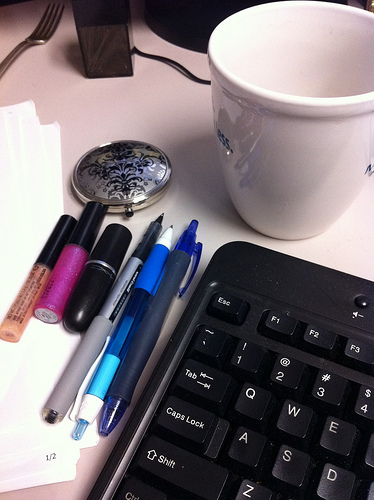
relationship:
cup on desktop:
[206, 0, 373, 240] [1, 0, 373, 500]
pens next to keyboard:
[68, 221, 175, 442] [86, 242, 373, 500]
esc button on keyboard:
[206, 289, 249, 326] [86, 242, 373, 500]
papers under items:
[1, 99, 99, 494] [1, 201, 173, 439]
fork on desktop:
[1, 0, 65, 78] [1, 0, 373, 500]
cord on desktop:
[134, 46, 211, 85] [1, 0, 373, 500]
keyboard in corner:
[86, 242, 373, 500] [86, 241, 373, 500]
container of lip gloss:
[34, 200, 109, 324] [33, 244, 88, 323]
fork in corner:
[1, 0, 65, 78] [1, 1, 70, 78]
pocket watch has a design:
[72, 139, 170, 218] [77, 142, 167, 200]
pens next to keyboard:
[43, 211, 202, 439] [86, 242, 373, 500]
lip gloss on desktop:
[34, 201, 107, 322] [1, 0, 373, 500]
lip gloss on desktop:
[1, 215, 78, 343] [1, 0, 373, 500]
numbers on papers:
[44, 452, 57, 462] [1, 99, 99, 494]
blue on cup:
[215, 127, 372, 177] [206, 0, 373, 240]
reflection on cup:
[209, 55, 269, 193] [206, 0, 373, 240]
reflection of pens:
[209, 55, 269, 193] [43, 211, 202, 439]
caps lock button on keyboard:
[150, 393, 231, 459] [86, 242, 373, 500]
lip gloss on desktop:
[33, 244, 88, 323] [1, 0, 373, 500]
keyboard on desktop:
[86, 242, 373, 500] [1, 0, 373, 500]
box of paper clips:
[72, 0, 132, 78] [93, 21, 121, 61]